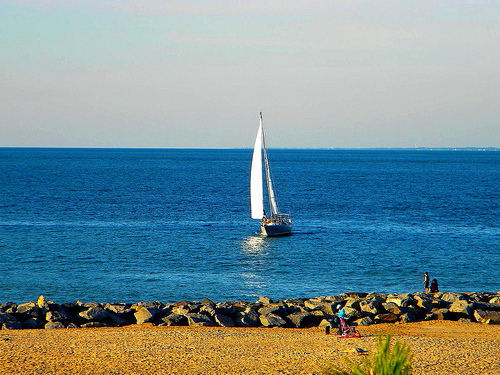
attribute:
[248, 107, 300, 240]
boat — white, full, populated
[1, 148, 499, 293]
water — blue, reflective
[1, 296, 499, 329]
rocks — gray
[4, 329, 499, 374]
beach — tan, amber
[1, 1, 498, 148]
sky — cloudy, blue